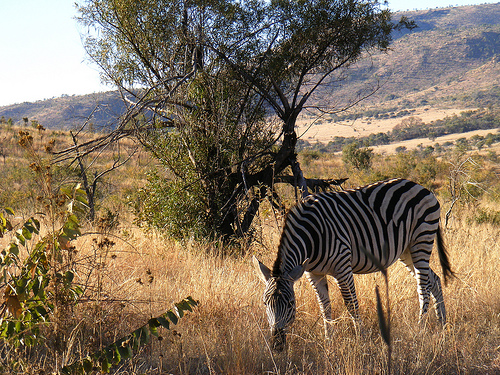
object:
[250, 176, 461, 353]
zebra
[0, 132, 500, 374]
field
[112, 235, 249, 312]
grass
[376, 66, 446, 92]
rocks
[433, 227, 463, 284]
tail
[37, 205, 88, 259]
leaves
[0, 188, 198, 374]
bush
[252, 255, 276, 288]
ear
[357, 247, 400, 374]
buds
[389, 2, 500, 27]
ridge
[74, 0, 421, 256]
trees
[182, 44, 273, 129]
leaves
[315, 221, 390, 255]
stripes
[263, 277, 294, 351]
head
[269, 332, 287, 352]
mouth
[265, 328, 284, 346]
nose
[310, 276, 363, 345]
front legs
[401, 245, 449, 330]
back legs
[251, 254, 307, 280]
ears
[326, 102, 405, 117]
trees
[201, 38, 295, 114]
branch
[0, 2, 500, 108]
sky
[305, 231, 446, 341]
legs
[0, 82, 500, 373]
landscape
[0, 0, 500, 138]
background